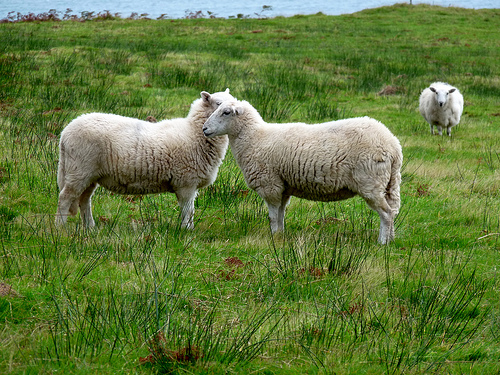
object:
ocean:
[0, 1, 500, 21]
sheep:
[201, 98, 403, 244]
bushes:
[2, 7, 269, 22]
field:
[0, 3, 500, 375]